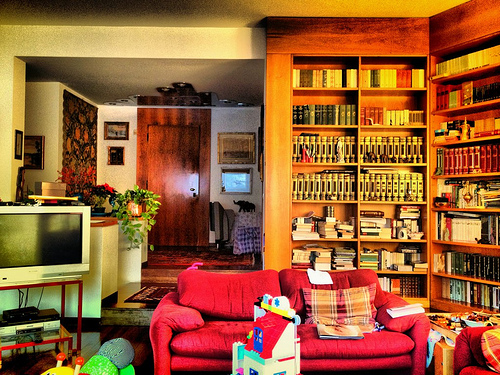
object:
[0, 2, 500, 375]
home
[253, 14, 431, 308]
bookcase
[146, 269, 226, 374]
sofa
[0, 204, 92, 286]
television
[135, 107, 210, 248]
door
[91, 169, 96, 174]
flowers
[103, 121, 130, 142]
picture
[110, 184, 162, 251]
plant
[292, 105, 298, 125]
book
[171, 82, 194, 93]
panel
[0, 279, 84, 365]
stand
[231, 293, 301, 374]
toy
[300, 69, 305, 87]
book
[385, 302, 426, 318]
book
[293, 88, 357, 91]
shelf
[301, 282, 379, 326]
pillow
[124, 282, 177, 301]
rug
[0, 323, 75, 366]
table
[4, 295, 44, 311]
electronics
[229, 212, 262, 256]
tablecloth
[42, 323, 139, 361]
toy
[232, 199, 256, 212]
elephant